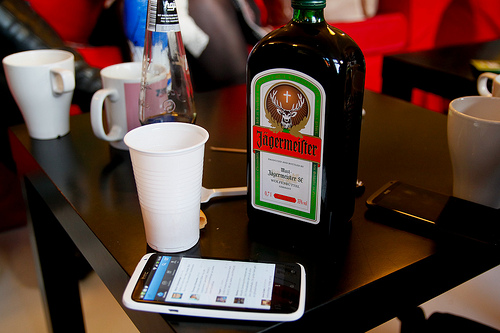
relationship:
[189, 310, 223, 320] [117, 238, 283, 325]
white cell phone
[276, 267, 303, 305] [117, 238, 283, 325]
back of phone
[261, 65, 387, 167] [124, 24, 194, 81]
glass grew bottle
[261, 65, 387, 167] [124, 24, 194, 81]
glass alcohol bottle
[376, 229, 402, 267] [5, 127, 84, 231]
brown colored table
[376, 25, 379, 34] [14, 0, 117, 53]
red colored couch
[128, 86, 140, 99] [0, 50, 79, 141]
pink coffee cup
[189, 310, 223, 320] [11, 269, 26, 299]
white colored floor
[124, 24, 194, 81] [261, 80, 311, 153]
bottle colored green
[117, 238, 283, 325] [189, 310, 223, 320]
phone with white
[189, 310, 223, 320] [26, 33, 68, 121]
white tall cup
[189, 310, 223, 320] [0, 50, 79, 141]
white pink cup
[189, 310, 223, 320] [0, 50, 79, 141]
white coffee cup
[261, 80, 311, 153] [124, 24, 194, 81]
green logo bottle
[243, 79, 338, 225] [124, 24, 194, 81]
label of bottle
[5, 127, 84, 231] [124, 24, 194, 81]
table with bottle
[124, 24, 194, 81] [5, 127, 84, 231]
bottle on table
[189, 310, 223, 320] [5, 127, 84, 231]
white cup table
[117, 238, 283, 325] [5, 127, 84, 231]
phone on table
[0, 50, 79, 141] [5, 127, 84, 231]
cup on table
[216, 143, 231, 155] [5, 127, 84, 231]
stick on table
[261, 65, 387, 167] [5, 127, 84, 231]
glass bottle table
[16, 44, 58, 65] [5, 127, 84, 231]
coffee mug table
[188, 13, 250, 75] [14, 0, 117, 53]
person on couch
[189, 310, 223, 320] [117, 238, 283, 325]
white back phone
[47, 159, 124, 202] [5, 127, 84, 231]
reflection on table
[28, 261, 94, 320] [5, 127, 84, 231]
legs on table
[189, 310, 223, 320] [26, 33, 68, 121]
white plastic cup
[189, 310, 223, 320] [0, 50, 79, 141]
white handle cup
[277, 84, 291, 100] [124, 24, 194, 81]
cross on bottle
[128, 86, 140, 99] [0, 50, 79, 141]
pink colored cup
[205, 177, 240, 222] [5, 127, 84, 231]
spoon on table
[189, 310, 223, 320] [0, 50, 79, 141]
white ceramic cup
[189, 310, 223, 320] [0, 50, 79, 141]
white cermaic cup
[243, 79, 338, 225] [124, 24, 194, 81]
label on bottle